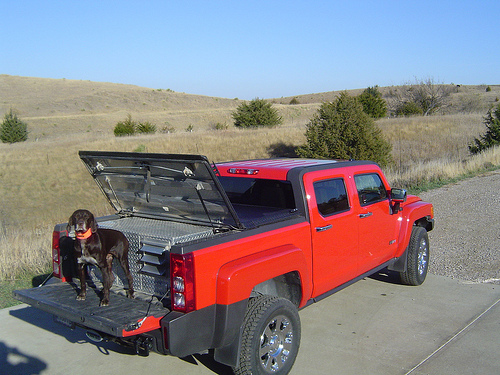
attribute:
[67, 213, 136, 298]
dog — standing, black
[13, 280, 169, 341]
tailgate — open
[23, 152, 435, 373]
truck — red, parked, sitting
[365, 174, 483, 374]
road — gravel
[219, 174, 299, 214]
window — tinted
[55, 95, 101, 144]
grass — brown, growing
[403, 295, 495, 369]
crack — small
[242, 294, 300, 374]
tire — black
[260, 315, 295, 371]
rims — shiny, silver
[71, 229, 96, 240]
collar — red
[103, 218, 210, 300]
tool box — silver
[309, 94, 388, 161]
tree — large, green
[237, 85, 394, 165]
trees — green, small, growing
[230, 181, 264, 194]
tint — black